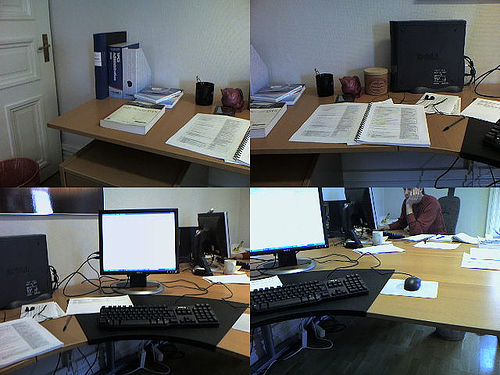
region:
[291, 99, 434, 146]
Open book on the table.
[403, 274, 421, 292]
Black computer mouse on pad.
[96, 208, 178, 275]
Computer monitor on the desk.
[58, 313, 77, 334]
Ink pen on the desk.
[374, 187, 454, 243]
Man sitting at desk.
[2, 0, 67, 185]
White door in the room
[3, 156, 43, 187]
Trash can in the room.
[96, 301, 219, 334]
Black keyboard on the desk.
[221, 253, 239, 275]
White coffee cup on the desk.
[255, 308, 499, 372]
Brown hard wood floor.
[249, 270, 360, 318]
the keyboard is black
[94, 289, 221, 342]
the keyboard is black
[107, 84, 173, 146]
books and papers on the table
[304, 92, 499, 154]
books and papers on the table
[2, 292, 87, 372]
books and papers on the table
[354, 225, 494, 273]
books and papers on the table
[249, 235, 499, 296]
books and papers on the table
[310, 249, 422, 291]
Black computer mouse with long wire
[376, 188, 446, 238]
Man at desk in maroon shirt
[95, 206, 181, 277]
Computer montior with white screen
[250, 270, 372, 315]
Black computer keyboard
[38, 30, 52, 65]
Brass handle of a door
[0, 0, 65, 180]
White door with decorative mouldings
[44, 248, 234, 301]
Wires surrounding a computer monitor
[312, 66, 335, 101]
Pencil holder with a writing instrument in it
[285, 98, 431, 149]
Open spiral notebook with lots of type on the pages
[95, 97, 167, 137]
Closed book with a cream colored cover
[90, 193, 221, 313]
the monitor is on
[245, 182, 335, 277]
the monitor is on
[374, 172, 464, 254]
a man behind the desk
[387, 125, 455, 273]
a man behind the desk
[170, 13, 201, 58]
this is a wall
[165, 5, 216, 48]
the wall is white in color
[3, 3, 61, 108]
this is a door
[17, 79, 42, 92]
the door is white in color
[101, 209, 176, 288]
this is a monitor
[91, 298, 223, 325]
this is a keyboard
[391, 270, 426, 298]
this is a mouse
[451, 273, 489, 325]
this is a table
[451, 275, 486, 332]
the table is wooden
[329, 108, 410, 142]
this is a book